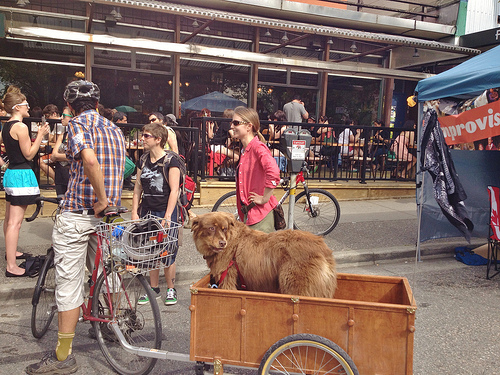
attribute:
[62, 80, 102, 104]
helmet — hard hat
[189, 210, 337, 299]
dog — light brown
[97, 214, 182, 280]
basket — silver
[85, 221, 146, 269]
basket — wire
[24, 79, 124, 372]
cyclist — pictured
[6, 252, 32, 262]
flats — black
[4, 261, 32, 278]
flats — black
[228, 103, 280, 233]
woman — pictured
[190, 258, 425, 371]
cart — brown, wooden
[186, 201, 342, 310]
dog — pictured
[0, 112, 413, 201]
metal fence — long, black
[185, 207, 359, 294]
dog — brown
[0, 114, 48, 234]
dress — sleeveless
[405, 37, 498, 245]
blue tent — part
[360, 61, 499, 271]
tent — pictured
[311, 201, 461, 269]
sidewalk — concrete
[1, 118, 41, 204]
outfit — black, blue, white